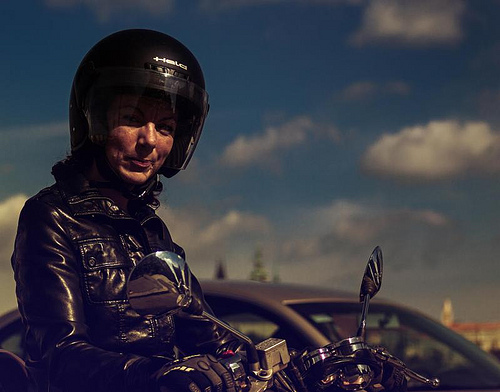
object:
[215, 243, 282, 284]
green trees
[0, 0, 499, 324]
sky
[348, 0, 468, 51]
clouds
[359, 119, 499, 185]
clouds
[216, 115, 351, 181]
clouds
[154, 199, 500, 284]
clouds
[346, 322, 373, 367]
handke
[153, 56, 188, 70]
logo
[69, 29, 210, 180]
helmet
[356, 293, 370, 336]
handle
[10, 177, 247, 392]
jacket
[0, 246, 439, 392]
bike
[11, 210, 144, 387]
arm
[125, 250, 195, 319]
mirror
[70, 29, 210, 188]
head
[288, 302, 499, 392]
windshield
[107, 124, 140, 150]
cheek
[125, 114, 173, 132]
eyes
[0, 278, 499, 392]
car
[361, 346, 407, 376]
handle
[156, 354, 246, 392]
glove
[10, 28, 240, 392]
bike rider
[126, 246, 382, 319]
mirror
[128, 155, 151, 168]
lips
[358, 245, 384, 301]
mirror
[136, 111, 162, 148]
nose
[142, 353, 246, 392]
hand